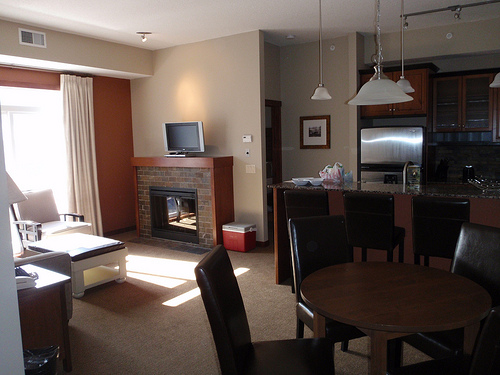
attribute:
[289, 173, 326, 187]
bowls — white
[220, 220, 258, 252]
icebox — white, red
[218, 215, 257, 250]
cooler — red and white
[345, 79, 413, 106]
shade — white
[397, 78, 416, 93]
shade — white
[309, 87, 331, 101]
shade — white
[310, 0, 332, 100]
ceiling lamp — white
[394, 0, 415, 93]
ceiling lamp — white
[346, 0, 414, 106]
ceiling lamp — white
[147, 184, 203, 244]
fireplace — brick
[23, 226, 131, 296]
coffee table — brown, white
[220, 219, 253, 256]
cooler — is red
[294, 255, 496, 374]
table — round, wooden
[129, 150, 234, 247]
mantel — wooden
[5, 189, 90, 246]
chair — framed, white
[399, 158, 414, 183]
faucet — tall silver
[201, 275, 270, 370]
chair — is black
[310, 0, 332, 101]
light — white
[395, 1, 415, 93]
light — white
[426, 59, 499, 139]
cabinets — glassy, wooden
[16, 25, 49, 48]
vent — white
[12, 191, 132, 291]
frame — wooden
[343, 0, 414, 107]
light — white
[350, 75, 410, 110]
cover — white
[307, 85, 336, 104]
cover — white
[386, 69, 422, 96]
cover — white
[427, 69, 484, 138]
cabinets — are wood